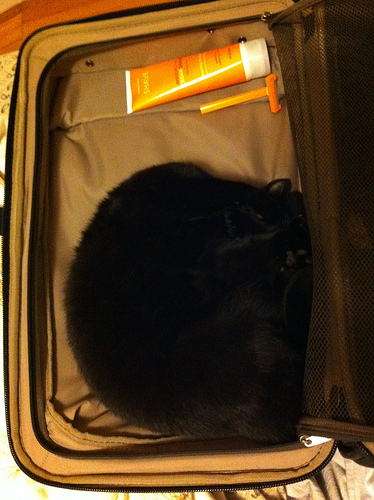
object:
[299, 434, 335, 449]
tab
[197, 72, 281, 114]
razor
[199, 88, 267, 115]
razor handle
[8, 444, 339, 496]
zipper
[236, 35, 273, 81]
whitecap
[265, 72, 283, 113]
razor blade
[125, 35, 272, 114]
tube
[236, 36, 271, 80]
cap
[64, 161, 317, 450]
cat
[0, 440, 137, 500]
fabric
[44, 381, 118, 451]
stitching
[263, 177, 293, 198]
cat ear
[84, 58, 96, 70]
button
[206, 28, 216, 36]
button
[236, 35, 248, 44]
button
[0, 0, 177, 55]
floor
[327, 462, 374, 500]
brown fabric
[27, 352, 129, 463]
corner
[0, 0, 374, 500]
case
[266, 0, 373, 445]
fabric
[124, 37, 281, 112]
items